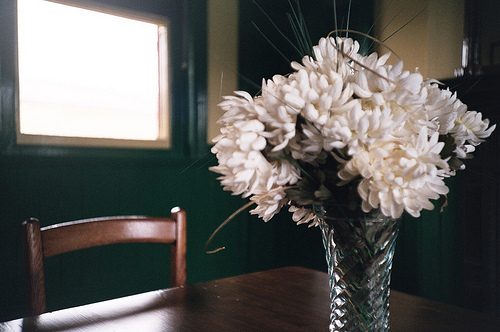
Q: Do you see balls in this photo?
A: No, there are no balls.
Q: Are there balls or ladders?
A: No, there are no balls or ladders.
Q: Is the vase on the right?
A: Yes, the vase is on the right of the image.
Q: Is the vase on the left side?
A: No, the vase is on the right of the image.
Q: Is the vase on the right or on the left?
A: The vase is on the right of the image.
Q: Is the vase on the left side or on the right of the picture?
A: The vase is on the right of the image.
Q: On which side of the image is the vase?
A: The vase is on the right of the image.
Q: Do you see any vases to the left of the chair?
A: No, the vase is to the right of the chair.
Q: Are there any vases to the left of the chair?
A: No, the vase is to the right of the chair.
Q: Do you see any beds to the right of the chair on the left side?
A: No, there is a vase to the right of the chair.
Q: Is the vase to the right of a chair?
A: Yes, the vase is to the right of a chair.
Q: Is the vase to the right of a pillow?
A: No, the vase is to the right of a chair.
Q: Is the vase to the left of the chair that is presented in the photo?
A: No, the vase is to the right of the chair.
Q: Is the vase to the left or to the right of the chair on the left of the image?
A: The vase is to the right of the chair.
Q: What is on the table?
A: The vase is on the table.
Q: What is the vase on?
A: The vase is on the table.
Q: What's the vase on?
A: The vase is on the table.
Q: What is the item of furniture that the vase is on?
A: The piece of furniture is a table.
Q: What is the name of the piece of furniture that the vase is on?
A: The piece of furniture is a table.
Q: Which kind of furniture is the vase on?
A: The vase is on the table.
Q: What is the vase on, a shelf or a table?
A: The vase is on a table.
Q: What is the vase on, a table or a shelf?
A: The vase is on a table.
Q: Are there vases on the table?
A: Yes, there is a vase on the table.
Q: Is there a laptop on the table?
A: No, there is a vase on the table.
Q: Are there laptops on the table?
A: No, there is a vase on the table.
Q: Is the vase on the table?
A: Yes, the vase is on the table.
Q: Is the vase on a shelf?
A: No, the vase is on the table.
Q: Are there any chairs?
A: Yes, there is a chair.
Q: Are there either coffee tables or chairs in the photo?
A: Yes, there is a chair.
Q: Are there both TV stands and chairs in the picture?
A: No, there is a chair but no TV stands.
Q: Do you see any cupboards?
A: No, there are no cupboards.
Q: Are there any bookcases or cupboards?
A: No, there are no cupboards or bookcases.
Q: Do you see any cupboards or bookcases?
A: No, there are no cupboards or bookcases.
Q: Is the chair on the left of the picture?
A: Yes, the chair is on the left of the image.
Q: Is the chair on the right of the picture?
A: No, the chair is on the left of the image.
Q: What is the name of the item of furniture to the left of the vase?
A: The piece of furniture is a chair.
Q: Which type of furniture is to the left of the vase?
A: The piece of furniture is a chair.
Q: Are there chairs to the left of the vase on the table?
A: Yes, there is a chair to the left of the vase.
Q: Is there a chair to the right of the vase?
A: No, the chair is to the left of the vase.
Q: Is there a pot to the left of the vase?
A: No, there is a chair to the left of the vase.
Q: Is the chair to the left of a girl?
A: No, the chair is to the left of a vase.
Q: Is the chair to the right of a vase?
A: No, the chair is to the left of a vase.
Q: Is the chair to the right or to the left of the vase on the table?
A: The chair is to the left of the vase.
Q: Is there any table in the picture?
A: Yes, there is a table.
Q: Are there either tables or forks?
A: Yes, there is a table.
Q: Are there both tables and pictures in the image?
A: No, there is a table but no pictures.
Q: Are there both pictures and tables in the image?
A: No, there is a table but no pictures.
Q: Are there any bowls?
A: No, there are no bowls.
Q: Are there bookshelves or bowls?
A: No, there are no bowls or bookshelves.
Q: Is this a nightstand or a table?
A: This is a table.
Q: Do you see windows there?
A: Yes, there is a window.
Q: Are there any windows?
A: Yes, there is a window.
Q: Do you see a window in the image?
A: Yes, there is a window.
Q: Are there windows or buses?
A: Yes, there is a window.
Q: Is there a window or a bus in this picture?
A: Yes, there is a window.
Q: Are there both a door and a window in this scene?
A: No, there is a window but no doors.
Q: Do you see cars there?
A: No, there are no cars.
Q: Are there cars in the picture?
A: No, there are no cars.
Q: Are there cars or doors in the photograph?
A: No, there are no cars or doors.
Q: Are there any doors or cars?
A: No, there are no cars or doors.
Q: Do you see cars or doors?
A: No, there are no cars or doors.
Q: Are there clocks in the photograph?
A: No, there are no clocks.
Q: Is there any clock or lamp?
A: No, there are no clocks or lamps.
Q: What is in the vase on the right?
A: The flower is in the vase.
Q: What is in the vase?
A: The flower is in the vase.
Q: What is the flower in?
A: The flower is in the vase.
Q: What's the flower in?
A: The flower is in the vase.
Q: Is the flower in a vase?
A: Yes, the flower is in a vase.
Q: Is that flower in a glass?
A: No, the flower is in a vase.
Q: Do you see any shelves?
A: No, there are no shelves.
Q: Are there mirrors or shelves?
A: No, there are no shelves or mirrors.